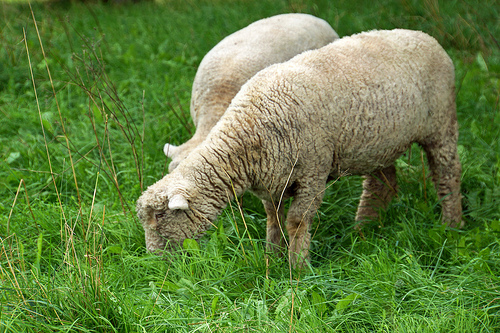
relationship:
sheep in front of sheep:
[133, 25, 464, 280] [160, 13, 339, 210]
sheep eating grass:
[160, 13, 339, 210] [1, 1, 498, 331]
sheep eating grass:
[133, 25, 464, 280] [1, 1, 498, 331]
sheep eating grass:
[93, 43, 475, 267] [9, 3, 424, 330]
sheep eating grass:
[160, 13, 339, 210] [9, 3, 424, 330]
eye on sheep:
[153, 210, 165, 220] [133, 25, 464, 280]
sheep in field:
[101, 14, 479, 277] [17, 10, 498, 322]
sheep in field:
[133, 25, 464, 280] [17, 10, 498, 322]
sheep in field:
[160, 13, 339, 210] [17, 10, 498, 322]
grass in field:
[339, 247, 417, 303] [17, 10, 498, 322]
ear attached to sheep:
[163, 188, 198, 214] [100, 26, 465, 285]